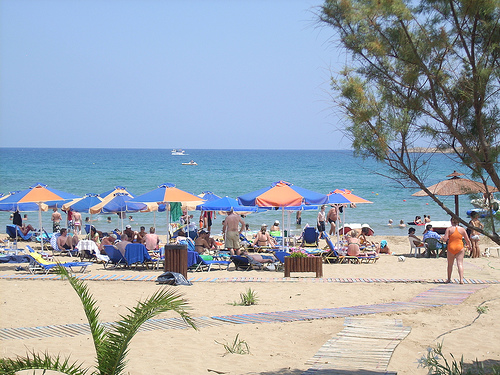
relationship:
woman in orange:
[444, 231, 463, 279] [449, 234, 466, 252]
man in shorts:
[221, 220, 251, 253] [223, 223, 237, 245]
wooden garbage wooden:
[167, 245, 189, 269] [168, 245, 189, 269]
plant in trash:
[287, 249, 311, 258] [276, 258, 339, 284]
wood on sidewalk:
[325, 342, 405, 367] [339, 316, 409, 373]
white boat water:
[169, 149, 196, 158] [217, 152, 282, 185]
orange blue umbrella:
[250, 186, 332, 208] [144, 191, 212, 203]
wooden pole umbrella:
[35, 200, 52, 249] [144, 191, 212, 203]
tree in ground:
[362, 33, 493, 138] [476, 256, 499, 279]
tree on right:
[362, 33, 493, 138] [245, 78, 303, 119]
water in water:
[217, 152, 282, 185] [217, 152, 282, 185]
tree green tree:
[362, 33, 493, 138] [362, 33, 493, 138]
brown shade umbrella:
[436, 174, 493, 190] [144, 191, 212, 203]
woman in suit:
[444, 231, 463, 279] [447, 224, 473, 255]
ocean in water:
[34, 157, 124, 176] [217, 152, 282, 185]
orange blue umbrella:
[449, 234, 466, 252] [144, 191, 212, 203]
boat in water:
[174, 148, 203, 173] [217, 152, 282, 185]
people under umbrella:
[80, 227, 179, 260] [144, 191, 212, 203]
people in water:
[80, 227, 179, 260] [217, 152, 282, 185]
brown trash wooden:
[436, 174, 493, 190] [168, 245, 189, 269]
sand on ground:
[274, 266, 310, 310] [476, 256, 499, 279]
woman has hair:
[426, 231, 479, 279] [445, 212, 463, 229]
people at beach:
[80, 227, 179, 260] [14, 285, 275, 337]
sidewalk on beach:
[339, 316, 409, 373] [14, 285, 275, 337]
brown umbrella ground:
[436, 174, 493, 190] [476, 256, 499, 279]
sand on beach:
[274, 266, 310, 310] [14, 285, 275, 337]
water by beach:
[217, 152, 282, 185] [14, 285, 275, 337]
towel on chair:
[72, 239, 108, 270] [26, 253, 113, 298]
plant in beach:
[287, 249, 311, 258] [14, 285, 275, 337]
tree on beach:
[362, 33, 493, 138] [14, 285, 275, 337]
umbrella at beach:
[144, 191, 212, 203] [14, 285, 275, 337]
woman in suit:
[426, 231, 479, 279] [447, 224, 473, 255]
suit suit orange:
[447, 224, 473, 255] [449, 234, 466, 252]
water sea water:
[217, 152, 282, 185] [217, 152, 282, 185]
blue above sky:
[96, 14, 210, 52] [211, 18, 278, 100]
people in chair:
[80, 227, 179, 260] [26, 253, 113, 298]